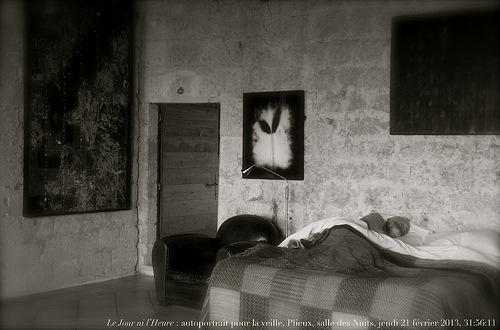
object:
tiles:
[51, 290, 148, 324]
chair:
[151, 214, 283, 311]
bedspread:
[200, 217, 498, 327]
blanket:
[200, 224, 499, 329]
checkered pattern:
[209, 264, 418, 330]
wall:
[0, 0, 500, 301]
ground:
[305, 127, 307, 184]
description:
[106, 318, 499, 329]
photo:
[0, 0, 497, 328]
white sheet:
[276, 214, 499, 269]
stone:
[3, 245, 127, 273]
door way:
[147, 102, 221, 266]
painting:
[388, 12, 500, 136]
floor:
[0, 274, 201, 329]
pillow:
[426, 229, 499, 256]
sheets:
[199, 217, 500, 329]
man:
[359, 212, 409, 238]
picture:
[241, 89, 306, 180]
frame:
[240, 89, 306, 180]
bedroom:
[0, 0, 500, 330]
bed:
[199, 212, 499, 328]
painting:
[21, 5, 135, 218]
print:
[262, 270, 322, 313]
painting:
[241, 90, 305, 179]